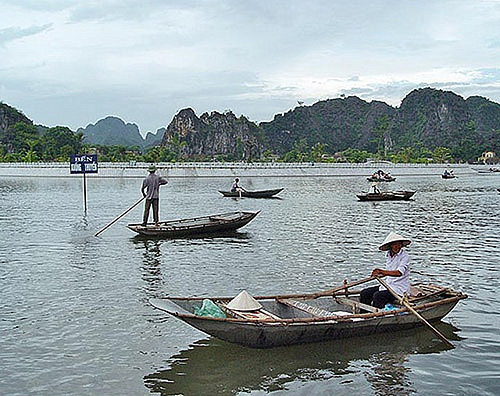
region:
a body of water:
[47, 285, 119, 338]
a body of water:
[89, 319, 116, 346]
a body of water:
[147, 351, 178, 369]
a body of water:
[63, 242, 97, 267]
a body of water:
[192, 255, 219, 272]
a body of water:
[305, 225, 335, 252]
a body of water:
[220, 228, 272, 268]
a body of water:
[465, 232, 491, 258]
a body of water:
[463, 280, 497, 307]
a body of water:
[419, 368, 439, 391]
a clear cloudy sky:
[79, 64, 115, 85]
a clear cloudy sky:
[136, 52, 163, 75]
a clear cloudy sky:
[180, 43, 212, 65]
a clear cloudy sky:
[255, 47, 290, 69]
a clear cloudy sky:
[307, 33, 347, 71]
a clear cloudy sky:
[363, 28, 394, 55]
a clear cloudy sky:
[415, 30, 444, 56]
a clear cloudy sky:
[455, 34, 490, 51]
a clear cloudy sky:
[460, 53, 482, 73]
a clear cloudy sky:
[412, 58, 452, 87]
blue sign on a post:
[68, 153, 98, 173]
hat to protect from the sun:
[378, 230, 411, 250]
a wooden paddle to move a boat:
[376, 274, 456, 351]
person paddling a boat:
[358, 231, 411, 312]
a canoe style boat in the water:
[145, 281, 469, 347]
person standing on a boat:
[140, 164, 168, 225]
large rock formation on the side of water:
[159, 106, 274, 163]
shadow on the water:
[143, 318, 470, 395]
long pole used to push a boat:
[94, 192, 149, 236]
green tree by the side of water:
[338, 147, 371, 162]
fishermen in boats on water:
[73, 136, 468, 354]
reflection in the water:
[153, 339, 458, 390]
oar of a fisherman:
[85, 195, 141, 243]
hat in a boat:
[219, 289, 271, 314]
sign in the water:
[61, 132, 118, 236]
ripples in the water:
[436, 212, 493, 282]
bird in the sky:
[283, 88, 309, 110]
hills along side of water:
[186, 87, 476, 160]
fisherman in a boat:
[356, 212, 413, 317]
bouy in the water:
[353, 161, 415, 212]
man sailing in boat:
[137, 225, 457, 364]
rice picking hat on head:
[363, 232, 413, 256]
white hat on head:
[382, 232, 412, 252]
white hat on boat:
[230, 289, 262, 312]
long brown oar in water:
[386, 282, 455, 355]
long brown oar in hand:
[317, 265, 387, 299]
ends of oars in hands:
[353, 258, 393, 294]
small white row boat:
[162, 278, 470, 350]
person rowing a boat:
[133, 219, 479, 363]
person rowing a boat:
[215, 178, 285, 209]